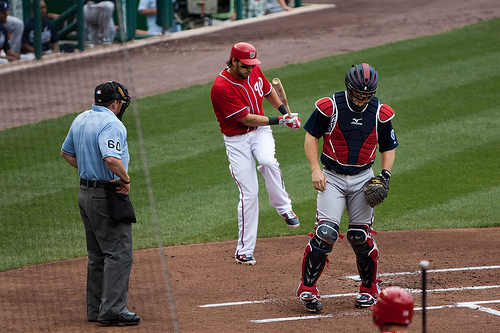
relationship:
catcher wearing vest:
[295, 60, 398, 320] [321, 92, 380, 174]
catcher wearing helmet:
[295, 60, 398, 320] [345, 60, 377, 93]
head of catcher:
[338, 43, 385, 122] [295, 60, 399, 312]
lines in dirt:
[197, 291, 304, 331] [2, 228, 497, 327]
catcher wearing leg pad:
[295, 60, 398, 320] [296, 216, 340, 293]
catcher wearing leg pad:
[295, 60, 398, 320] [348, 222, 379, 292]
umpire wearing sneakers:
[61, 75, 161, 325] [355, 277, 377, 307]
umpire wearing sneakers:
[61, 75, 161, 325] [301, 289, 328, 322]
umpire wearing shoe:
[61, 75, 161, 325] [234, 251, 258, 266]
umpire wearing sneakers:
[61, 75, 161, 325] [280, 199, 299, 224]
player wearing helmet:
[206, 39, 302, 268] [229, 41, 265, 66]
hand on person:
[299, 164, 337, 196] [305, 50, 392, 302]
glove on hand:
[363, 167, 398, 214] [366, 175, 387, 200]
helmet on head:
[337, 62, 387, 104] [338, 56, 385, 106]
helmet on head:
[226, 37, 269, 80] [229, 38, 265, 78]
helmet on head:
[89, 82, 132, 112] [91, 75, 130, 115]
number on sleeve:
[106, 137, 122, 151] [96, 125, 124, 161]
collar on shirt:
[88, 100, 110, 112] [61, 103, 137, 182]